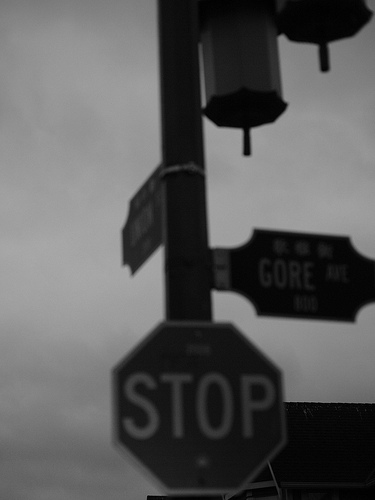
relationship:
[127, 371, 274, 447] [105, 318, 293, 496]
stop on sign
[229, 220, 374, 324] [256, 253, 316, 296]
sign reads gore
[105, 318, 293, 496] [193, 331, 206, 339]
sign has a screw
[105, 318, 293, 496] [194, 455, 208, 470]
sign has a screw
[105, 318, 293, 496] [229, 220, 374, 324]
sign on top of sign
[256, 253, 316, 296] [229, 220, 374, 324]
gore on sign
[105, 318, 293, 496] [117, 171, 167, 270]
sign and road sign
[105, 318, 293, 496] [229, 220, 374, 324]
sign and sign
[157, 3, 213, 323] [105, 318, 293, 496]
pole holding up sign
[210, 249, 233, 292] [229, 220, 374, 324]
hinge connecting sign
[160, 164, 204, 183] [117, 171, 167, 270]
hinge connecting road sign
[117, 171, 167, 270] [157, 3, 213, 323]
road sign and pole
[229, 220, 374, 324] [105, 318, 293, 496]
sign above sign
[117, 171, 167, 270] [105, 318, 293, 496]
road sign above sign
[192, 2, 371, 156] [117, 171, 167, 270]
lamps above road sign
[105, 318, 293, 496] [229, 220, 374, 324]
sign below sign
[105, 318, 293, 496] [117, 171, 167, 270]
sign below road sign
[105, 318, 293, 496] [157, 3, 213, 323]
sign on pole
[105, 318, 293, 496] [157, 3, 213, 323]
sign on a pole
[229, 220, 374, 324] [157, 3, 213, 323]
sign on pole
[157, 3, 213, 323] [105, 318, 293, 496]
pole with sign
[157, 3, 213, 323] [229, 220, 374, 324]
pole with sign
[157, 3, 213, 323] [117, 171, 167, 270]
pole with road sign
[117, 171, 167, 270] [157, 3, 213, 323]
road sign on pole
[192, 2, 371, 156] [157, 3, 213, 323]
lamps on pole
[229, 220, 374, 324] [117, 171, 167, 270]
sign and road sign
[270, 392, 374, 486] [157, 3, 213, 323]
roof behind pole